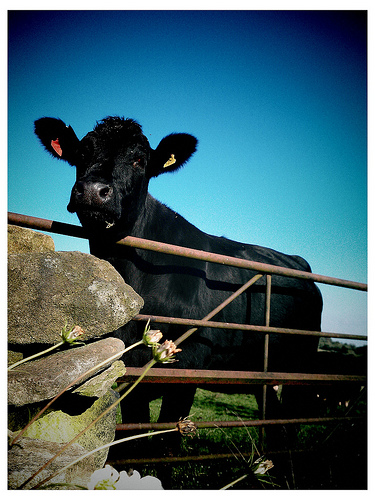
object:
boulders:
[7, 223, 144, 350]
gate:
[159, 242, 267, 462]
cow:
[31, 113, 324, 458]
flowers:
[57, 317, 89, 350]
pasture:
[150, 375, 333, 476]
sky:
[201, 13, 366, 227]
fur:
[81, 111, 149, 147]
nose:
[66, 180, 113, 215]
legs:
[146, 366, 202, 463]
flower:
[247, 443, 276, 478]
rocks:
[6, 334, 129, 408]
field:
[117, 392, 367, 490]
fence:
[136, 235, 367, 477]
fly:
[8, 163, 63, 210]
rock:
[8, 336, 126, 434]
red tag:
[49, 140, 63, 156]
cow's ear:
[31, 114, 79, 166]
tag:
[160, 152, 179, 172]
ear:
[150, 131, 199, 178]